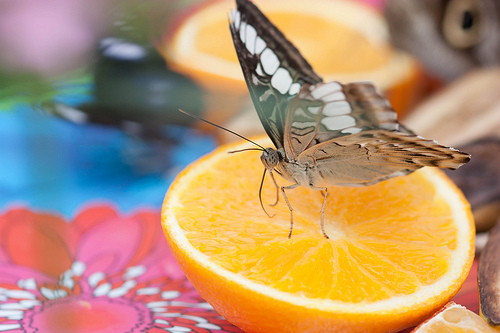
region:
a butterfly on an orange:
[164, 0, 477, 329]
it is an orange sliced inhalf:
[157, 117, 479, 328]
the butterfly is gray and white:
[177, 3, 472, 238]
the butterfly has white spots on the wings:
[227, 0, 400, 157]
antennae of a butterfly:
[173, 102, 273, 171]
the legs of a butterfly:
[256, 162, 337, 243]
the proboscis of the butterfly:
[261, 146, 281, 209]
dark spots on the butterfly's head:
[258, 146, 282, 169]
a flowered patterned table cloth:
[5, 77, 499, 331]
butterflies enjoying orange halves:
[63, 2, 485, 331]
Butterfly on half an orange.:
[172, 0, 470, 240]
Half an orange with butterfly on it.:
[162, 131, 477, 331]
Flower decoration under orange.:
[1, 203, 253, 330]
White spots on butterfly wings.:
[312, 82, 360, 139]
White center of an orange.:
[310, 215, 354, 243]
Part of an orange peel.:
[215, 291, 258, 317]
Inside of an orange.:
[372, 199, 431, 251]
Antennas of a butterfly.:
[177, 109, 265, 155]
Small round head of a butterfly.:
[261, 149, 279, 167]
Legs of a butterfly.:
[280, 182, 330, 240]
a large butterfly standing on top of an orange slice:
[218, 1, 478, 235]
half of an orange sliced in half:
[160, 140, 465, 330]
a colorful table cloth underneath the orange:
[8, 68, 243, 325]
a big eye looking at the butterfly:
[434, 5, 480, 45]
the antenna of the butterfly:
[171, 102, 266, 160]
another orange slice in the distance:
[195, 4, 398, 89]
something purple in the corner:
[3, 2, 93, 75]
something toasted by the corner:
[473, 229, 499, 327]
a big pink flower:
[8, 200, 189, 331]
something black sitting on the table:
[91, 35, 206, 131]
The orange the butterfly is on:
[160, 132, 477, 332]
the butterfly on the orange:
[179, 1, 476, 243]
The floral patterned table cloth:
[0, 54, 235, 332]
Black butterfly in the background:
[39, 26, 216, 153]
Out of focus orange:
[164, 0, 416, 111]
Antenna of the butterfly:
[175, 104, 265, 157]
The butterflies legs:
[268, 173, 340, 246]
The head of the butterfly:
[259, 143, 279, 173]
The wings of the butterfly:
[224, 0, 471, 180]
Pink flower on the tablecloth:
[0, 201, 221, 332]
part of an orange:
[381, 237, 434, 277]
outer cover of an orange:
[236, 281, 271, 310]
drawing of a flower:
[30, 229, 130, 319]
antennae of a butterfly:
[213, 123, 261, 159]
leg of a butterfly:
[275, 177, 300, 244]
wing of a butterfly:
[345, 134, 417, 171]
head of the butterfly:
[263, 160, 276, 170]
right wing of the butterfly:
[262, 64, 300, 116]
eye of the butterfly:
[267, 152, 277, 162]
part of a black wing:
[117, 83, 159, 121]